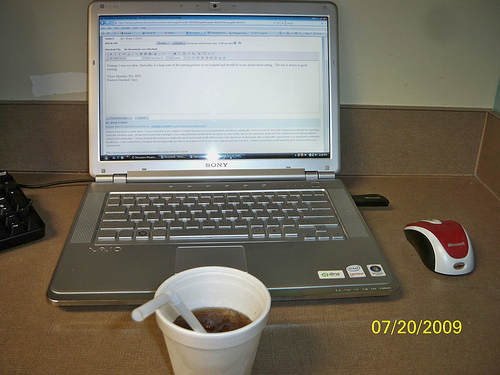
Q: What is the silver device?
A: Laptop.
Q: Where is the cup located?
A: In front of the laptop.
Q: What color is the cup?
A: White.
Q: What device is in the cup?
A: A straw.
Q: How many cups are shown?
A: One.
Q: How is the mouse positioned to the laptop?
A: To the right of it.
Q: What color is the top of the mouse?
A: Red.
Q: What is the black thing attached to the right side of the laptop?
A: Memory Stick.